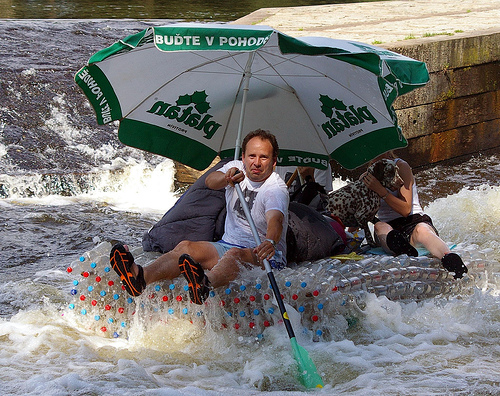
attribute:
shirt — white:
[220, 160, 289, 260]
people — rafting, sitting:
[167, 141, 430, 285]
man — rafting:
[212, 134, 294, 267]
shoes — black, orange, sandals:
[96, 236, 213, 311]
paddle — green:
[266, 291, 334, 386]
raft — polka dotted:
[62, 227, 456, 337]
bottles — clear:
[357, 277, 400, 294]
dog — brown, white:
[327, 165, 406, 223]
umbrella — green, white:
[77, 29, 419, 162]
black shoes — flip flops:
[388, 235, 480, 285]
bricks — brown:
[372, 14, 475, 83]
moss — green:
[424, 66, 498, 123]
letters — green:
[311, 102, 364, 130]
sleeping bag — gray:
[163, 186, 201, 243]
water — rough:
[28, 138, 117, 234]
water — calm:
[19, 5, 87, 17]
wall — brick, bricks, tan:
[474, 11, 493, 36]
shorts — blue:
[204, 230, 272, 275]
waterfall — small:
[23, 92, 134, 220]